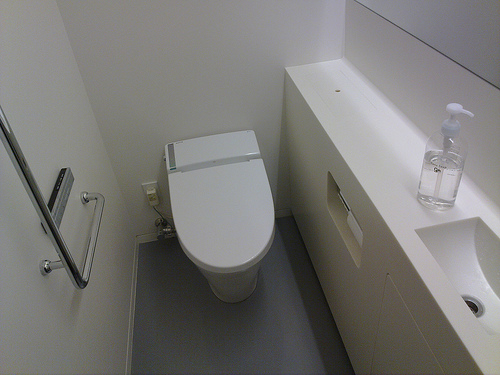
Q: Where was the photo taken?
A: It was taken at the bathroom.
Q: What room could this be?
A: It is a bathroom.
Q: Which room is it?
A: It is a bathroom.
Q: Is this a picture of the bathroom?
A: Yes, it is showing the bathroom.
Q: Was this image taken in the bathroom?
A: Yes, it was taken in the bathroom.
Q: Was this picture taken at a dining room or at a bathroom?
A: It was taken at a bathroom.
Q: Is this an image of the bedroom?
A: No, the picture is showing the bathroom.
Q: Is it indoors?
A: Yes, it is indoors.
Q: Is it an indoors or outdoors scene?
A: It is indoors.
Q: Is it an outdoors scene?
A: No, it is indoors.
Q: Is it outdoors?
A: No, it is indoors.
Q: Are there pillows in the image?
A: No, there are no pillows.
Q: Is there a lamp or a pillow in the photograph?
A: No, there are no pillows or lamps.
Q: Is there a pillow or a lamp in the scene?
A: No, there are no pillows or lamps.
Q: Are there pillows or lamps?
A: No, there are no pillows or lamps.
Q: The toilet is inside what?
A: The toilet is inside the bathroom.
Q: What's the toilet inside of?
A: The toilet is inside the bathroom.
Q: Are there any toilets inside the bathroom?
A: Yes, there is a toilet inside the bathroom.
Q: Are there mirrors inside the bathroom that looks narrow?
A: No, there is a toilet inside the bathroom.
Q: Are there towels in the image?
A: No, there are no towels.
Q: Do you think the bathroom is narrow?
A: Yes, the bathroom is narrow.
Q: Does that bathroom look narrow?
A: Yes, the bathroom is narrow.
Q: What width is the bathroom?
A: The bathroom is narrow.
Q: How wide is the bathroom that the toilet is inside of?
A: The bathroom is narrow.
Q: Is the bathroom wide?
A: No, the bathroom is narrow.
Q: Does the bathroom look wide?
A: No, the bathroom is narrow.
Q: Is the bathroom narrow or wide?
A: The bathroom is narrow.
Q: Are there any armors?
A: No, there are no armors.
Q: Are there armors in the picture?
A: No, there are no armors.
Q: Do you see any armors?
A: No, there are no armors.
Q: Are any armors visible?
A: No, there are no armors.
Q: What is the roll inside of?
A: The roll is inside the bathroom.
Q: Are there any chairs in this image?
A: No, there are no chairs.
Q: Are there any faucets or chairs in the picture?
A: No, there are no chairs or faucets.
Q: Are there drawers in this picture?
A: No, there are no drawers.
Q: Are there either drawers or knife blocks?
A: No, there are no drawers or knife blocks.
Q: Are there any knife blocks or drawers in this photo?
A: No, there are no drawers or knife blocks.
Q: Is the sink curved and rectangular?
A: Yes, the sink is curved and rectangular.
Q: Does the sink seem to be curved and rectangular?
A: Yes, the sink is curved and rectangular.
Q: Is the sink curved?
A: Yes, the sink is curved.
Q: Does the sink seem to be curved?
A: Yes, the sink is curved.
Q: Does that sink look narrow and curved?
A: Yes, the sink is narrow and curved.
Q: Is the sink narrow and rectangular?
A: Yes, the sink is narrow and rectangular.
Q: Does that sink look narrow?
A: Yes, the sink is narrow.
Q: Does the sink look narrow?
A: Yes, the sink is narrow.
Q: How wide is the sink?
A: The sink is narrow.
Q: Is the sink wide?
A: No, the sink is narrow.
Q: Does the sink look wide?
A: No, the sink is narrow.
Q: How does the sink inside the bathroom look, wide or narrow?
A: The sink is narrow.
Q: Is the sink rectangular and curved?
A: Yes, the sink is rectangular and curved.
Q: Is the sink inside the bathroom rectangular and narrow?
A: Yes, the sink is rectangular and narrow.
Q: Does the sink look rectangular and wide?
A: No, the sink is rectangular but narrow.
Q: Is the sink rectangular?
A: Yes, the sink is rectangular.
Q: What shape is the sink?
A: The sink is rectangular.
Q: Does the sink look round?
A: No, the sink is rectangular.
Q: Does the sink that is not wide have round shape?
A: No, the sink is rectangular.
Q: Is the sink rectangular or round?
A: The sink is rectangular.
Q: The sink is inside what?
A: The sink is inside the bathroom.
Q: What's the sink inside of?
A: The sink is inside the bathroom.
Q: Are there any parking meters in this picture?
A: No, there are no parking meters.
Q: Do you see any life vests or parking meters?
A: No, there are no parking meters or life vests.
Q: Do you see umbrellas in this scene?
A: No, there are no umbrellas.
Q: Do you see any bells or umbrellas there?
A: No, there are no umbrellas or bells.